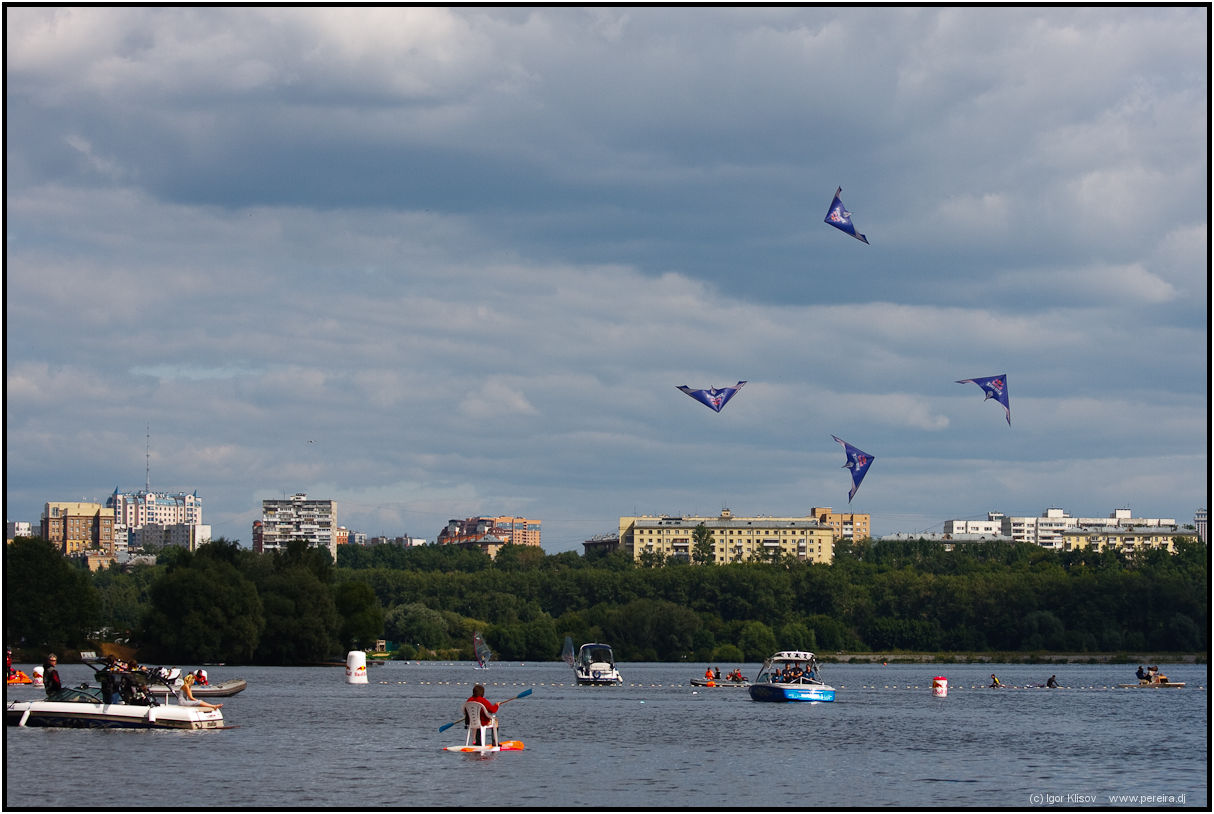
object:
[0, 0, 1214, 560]
clouds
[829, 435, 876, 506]
kite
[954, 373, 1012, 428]
kite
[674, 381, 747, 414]
kite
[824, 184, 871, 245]
kite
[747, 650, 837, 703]
boat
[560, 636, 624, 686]
boat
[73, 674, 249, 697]
boat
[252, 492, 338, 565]
building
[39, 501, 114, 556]
building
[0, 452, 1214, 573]
distance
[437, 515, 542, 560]
building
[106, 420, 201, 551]
building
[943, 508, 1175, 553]
building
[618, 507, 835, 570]
building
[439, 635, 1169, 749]
people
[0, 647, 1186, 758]
people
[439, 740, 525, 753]
float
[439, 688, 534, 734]
oar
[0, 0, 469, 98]
cloud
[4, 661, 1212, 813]
river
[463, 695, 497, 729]
shirt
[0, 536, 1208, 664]
trees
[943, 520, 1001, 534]
building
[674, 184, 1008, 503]
flags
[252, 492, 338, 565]
apartment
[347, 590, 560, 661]
bushes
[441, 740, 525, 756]
boat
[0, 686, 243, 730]
barge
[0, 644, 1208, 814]
water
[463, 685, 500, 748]
man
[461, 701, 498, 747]
chair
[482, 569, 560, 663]
leaves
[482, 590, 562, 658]
tree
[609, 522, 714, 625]
tree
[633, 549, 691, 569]
leaves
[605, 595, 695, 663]
leaves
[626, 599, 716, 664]
tree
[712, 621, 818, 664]
tree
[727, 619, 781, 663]
leaves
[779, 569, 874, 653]
leaves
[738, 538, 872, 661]
tree